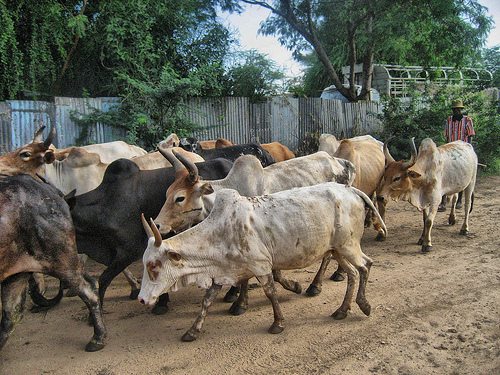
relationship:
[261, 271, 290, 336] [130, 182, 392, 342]
leg of cow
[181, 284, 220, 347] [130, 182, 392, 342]
leg of cow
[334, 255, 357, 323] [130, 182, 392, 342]
leg of cow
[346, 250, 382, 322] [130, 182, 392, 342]
leg of cow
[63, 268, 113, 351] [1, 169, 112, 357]
leg of cow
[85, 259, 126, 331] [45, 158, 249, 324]
leg of cow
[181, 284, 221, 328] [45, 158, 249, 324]
leg of cow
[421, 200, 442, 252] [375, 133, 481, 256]
leg of cow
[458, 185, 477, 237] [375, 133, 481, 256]
leg of cow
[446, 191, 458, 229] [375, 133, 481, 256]
leg of cow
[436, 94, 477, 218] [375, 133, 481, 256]
man herding cow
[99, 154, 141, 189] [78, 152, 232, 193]
hump on back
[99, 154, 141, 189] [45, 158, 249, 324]
hump on cow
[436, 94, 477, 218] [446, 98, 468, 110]
man wearing hat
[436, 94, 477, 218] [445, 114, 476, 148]
man wearing shirt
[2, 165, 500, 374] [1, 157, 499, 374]
dirt on ground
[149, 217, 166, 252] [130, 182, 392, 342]
horns on cow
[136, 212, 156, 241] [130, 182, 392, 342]
horns on cow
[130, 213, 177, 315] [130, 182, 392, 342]
head of cow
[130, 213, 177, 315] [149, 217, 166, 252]
head with horns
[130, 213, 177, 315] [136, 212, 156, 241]
head with horns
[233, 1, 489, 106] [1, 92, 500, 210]
trees behind fence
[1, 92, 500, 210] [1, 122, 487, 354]
fence behind group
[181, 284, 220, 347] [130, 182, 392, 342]
leg on cow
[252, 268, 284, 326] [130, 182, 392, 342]
leg on cow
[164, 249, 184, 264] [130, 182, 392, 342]
ear on cow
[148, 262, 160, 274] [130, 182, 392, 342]
eye on cow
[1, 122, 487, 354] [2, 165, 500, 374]
group in dirt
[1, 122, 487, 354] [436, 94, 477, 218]
group belonging to man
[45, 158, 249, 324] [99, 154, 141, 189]
cow has hump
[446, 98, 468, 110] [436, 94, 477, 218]
hat on man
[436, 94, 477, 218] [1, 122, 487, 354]
man tending group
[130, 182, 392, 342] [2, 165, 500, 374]
cow on dirt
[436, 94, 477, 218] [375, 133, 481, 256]
man next to cow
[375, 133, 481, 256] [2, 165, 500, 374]
cow on dirt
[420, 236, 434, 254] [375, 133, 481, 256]
hoof on cow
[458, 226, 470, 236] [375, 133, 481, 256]
hoof on cow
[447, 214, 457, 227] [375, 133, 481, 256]
hoof on cow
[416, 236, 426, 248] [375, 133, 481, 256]
hoof on cow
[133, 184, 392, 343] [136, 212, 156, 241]
cow has horns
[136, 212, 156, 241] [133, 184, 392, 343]
horns are on cow